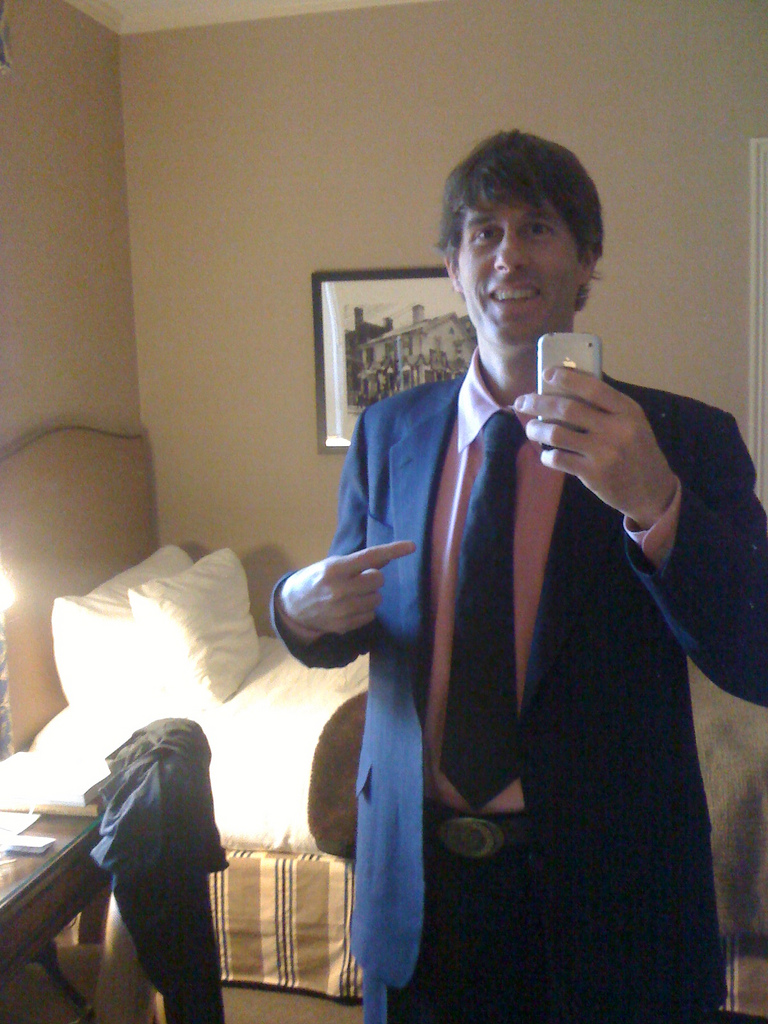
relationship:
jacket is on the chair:
[82, 715, 229, 1024] [19, 710, 204, 1011]